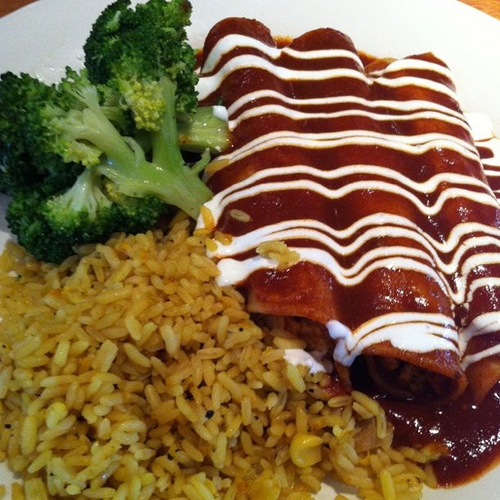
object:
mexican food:
[184, 17, 498, 488]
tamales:
[216, 46, 463, 364]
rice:
[0, 205, 451, 495]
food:
[0, 0, 499, 498]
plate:
[1, 0, 498, 498]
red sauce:
[371, 383, 498, 490]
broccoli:
[4, 0, 231, 263]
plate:
[420, 9, 484, 41]